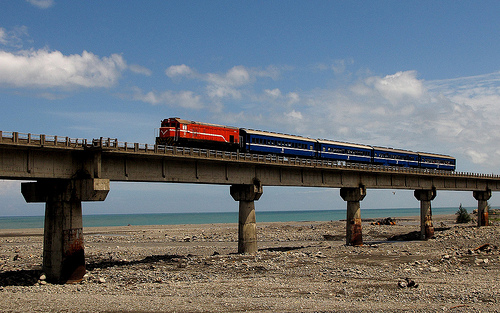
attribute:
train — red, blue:
[154, 114, 458, 171]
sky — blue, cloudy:
[1, 3, 498, 148]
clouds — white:
[3, 51, 127, 92]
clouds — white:
[370, 72, 425, 110]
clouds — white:
[161, 58, 288, 86]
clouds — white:
[20, 0, 60, 10]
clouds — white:
[129, 89, 208, 113]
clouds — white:
[1, 22, 32, 52]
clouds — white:
[432, 69, 499, 102]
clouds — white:
[308, 54, 363, 76]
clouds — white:
[458, 154, 500, 169]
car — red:
[157, 116, 242, 154]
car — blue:
[238, 129, 321, 159]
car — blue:
[316, 135, 372, 164]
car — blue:
[371, 145, 419, 167]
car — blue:
[417, 153, 457, 169]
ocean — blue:
[1, 202, 494, 227]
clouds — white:
[278, 108, 315, 134]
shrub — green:
[452, 203, 473, 225]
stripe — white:
[159, 128, 464, 168]